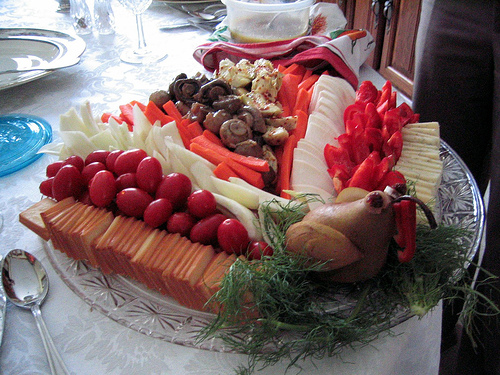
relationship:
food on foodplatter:
[23, 30, 424, 275] [17, 56, 486, 353]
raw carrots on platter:
[102, 99, 267, 194] [33, 139, 484, 367]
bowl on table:
[218, 0, 320, 49] [0, 0, 442, 374]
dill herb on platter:
[383, 254, 455, 299] [108, 302, 185, 350]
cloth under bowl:
[190, 15, 370, 66] [218, 0, 320, 49]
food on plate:
[23, 30, 424, 275] [38, 135, 485, 354]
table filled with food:
[0, 0, 442, 374] [19, 57, 499, 373]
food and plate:
[19, 57, 499, 373] [37, 92, 484, 356]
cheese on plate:
[23, 190, 268, 320] [73, 47, 483, 345]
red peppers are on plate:
[325, 77, 416, 266] [36, 58, 486, 355]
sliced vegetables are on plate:
[71, 90, 284, 231] [78, 262, 427, 357]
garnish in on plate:
[227, 262, 425, 358] [37, 92, 484, 356]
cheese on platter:
[20, 192, 245, 317] [35, 102, 485, 353]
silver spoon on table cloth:
[7, 246, 85, 367] [77, 327, 143, 373]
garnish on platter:
[206, 186, 473, 358] [36, 123, 476, 350]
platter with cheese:
[17, 54, 484, 364] [197, 245, 261, 320]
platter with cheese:
[17, 54, 484, 364] [382, 117, 448, 229]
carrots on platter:
[99, 98, 271, 191] [17, 54, 484, 364]